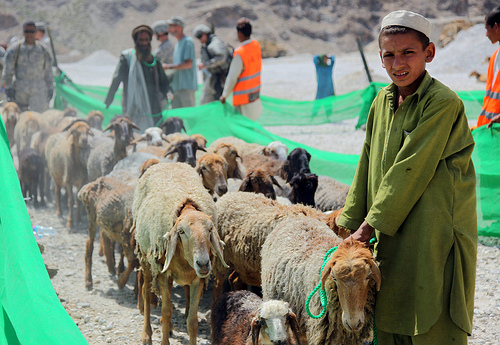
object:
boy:
[333, 8, 478, 345]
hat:
[376, 9, 434, 41]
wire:
[303, 241, 376, 345]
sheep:
[213, 190, 355, 296]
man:
[0, 20, 55, 114]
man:
[160, 18, 197, 108]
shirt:
[174, 36, 197, 91]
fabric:
[54, 74, 500, 238]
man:
[310, 53, 336, 124]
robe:
[312, 52, 335, 116]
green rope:
[304, 236, 379, 345]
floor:
[247, 114, 368, 157]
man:
[219, 20, 261, 120]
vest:
[231, 37, 262, 107]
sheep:
[208, 288, 303, 345]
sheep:
[285, 146, 319, 206]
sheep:
[128, 160, 231, 345]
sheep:
[255, 214, 381, 345]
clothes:
[335, 70, 476, 345]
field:
[0, 60, 500, 345]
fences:
[44, 67, 500, 234]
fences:
[0, 118, 90, 344]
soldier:
[193, 24, 234, 101]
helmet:
[204, 101, 227, 116]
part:
[4, 145, 144, 238]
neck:
[307, 245, 333, 324]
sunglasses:
[22, 28, 38, 35]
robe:
[333, 70, 479, 336]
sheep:
[75, 174, 138, 291]